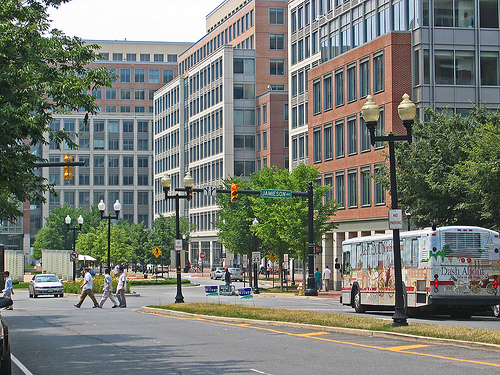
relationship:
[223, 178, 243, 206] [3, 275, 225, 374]
light on road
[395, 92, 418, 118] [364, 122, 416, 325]
light on pole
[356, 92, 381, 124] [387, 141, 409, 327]
light on lampposts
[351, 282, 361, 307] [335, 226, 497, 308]
tire on bus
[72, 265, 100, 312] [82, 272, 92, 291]
man wearing shirt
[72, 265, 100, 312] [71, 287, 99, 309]
man wearing pants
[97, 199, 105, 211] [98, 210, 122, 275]
light on pole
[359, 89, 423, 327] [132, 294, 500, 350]
lampposts with glass shades in island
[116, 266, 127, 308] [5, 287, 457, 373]
people crossing street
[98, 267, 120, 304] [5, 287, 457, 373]
person crossing street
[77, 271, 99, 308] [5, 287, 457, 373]
person crossing street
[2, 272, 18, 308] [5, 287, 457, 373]
person crossing street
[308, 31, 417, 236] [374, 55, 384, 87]
panel with window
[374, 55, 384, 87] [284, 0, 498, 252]
window over building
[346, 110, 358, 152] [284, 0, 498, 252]
window over building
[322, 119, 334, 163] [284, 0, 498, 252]
window over building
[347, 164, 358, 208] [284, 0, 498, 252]
window over building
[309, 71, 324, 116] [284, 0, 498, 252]
window over building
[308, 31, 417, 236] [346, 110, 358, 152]
panel with window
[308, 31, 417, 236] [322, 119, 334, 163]
panel with window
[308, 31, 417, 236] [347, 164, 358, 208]
panel with window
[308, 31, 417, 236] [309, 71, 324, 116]
panel with window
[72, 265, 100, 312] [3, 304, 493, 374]
man crossing street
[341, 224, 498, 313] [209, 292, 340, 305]
bus driving down street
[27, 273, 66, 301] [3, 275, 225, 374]
car on road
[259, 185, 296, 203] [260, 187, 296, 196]
street sign hanging from post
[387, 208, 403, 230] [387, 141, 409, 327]
sign on lampposts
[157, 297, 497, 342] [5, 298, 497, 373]
island dividing street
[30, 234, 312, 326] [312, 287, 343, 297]
people walking on sidewalk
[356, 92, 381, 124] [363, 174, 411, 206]
light on a pole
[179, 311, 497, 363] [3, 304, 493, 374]
stripes on street